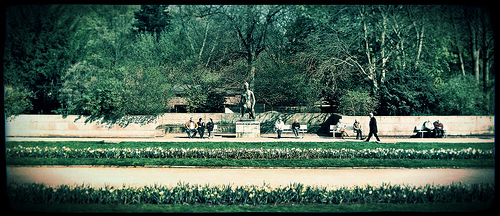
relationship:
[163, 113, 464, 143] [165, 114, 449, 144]
people on bench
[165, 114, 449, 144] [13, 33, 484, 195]
bench in park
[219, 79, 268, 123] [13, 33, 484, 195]
statue in park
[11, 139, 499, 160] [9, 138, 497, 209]
flowers in row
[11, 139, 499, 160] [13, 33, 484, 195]
flowers in park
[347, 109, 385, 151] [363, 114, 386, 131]
man wearing jacket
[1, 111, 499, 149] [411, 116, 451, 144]
wall behind sitters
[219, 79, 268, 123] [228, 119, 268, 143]
statue on stand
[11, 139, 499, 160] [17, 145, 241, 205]
flowers in group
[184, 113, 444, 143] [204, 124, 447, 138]
people on bench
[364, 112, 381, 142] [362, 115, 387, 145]
man wearing black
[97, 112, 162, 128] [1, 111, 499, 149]
shade on wall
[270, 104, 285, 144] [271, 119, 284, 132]
person wearing shirt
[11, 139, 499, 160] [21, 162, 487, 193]
flowers around pond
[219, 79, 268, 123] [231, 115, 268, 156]
statue on pedestal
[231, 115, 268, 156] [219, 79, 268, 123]
pedestal holding statue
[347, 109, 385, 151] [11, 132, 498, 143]
man on sidewalk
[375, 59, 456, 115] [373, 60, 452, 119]
tree with leaves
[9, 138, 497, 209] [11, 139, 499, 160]
row of flowers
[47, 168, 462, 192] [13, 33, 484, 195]
water in park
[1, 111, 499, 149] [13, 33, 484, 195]
wall in park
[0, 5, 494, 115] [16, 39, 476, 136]
tree in background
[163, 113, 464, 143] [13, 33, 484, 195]
people in park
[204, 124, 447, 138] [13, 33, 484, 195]
bench in park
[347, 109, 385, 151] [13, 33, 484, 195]
man in park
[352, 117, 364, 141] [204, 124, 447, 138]
man on bench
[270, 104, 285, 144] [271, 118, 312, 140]
person on bench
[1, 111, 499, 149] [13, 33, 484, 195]
wall surrounding park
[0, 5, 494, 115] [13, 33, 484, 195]
tree lining park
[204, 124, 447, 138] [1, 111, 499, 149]
bench near wall